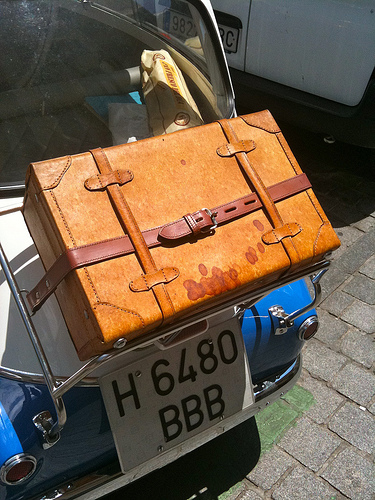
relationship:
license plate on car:
[148, 11, 263, 44] [152, 12, 361, 107]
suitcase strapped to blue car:
[18, 108, 343, 360] [0, 1, 339, 500]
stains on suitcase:
[171, 219, 266, 304] [18, 108, 343, 360]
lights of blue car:
[2, 450, 39, 486] [0, 1, 339, 500]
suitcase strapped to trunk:
[18, 108, 343, 360] [5, 149, 337, 440]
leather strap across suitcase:
[26, 152, 313, 290] [18, 108, 343, 360]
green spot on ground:
[240, 376, 320, 454] [229, 350, 374, 494]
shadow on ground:
[284, 115, 374, 228] [215, 119, 374, 498]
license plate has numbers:
[97, 316, 255, 473] [148, 327, 240, 394]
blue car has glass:
[0, 1, 339, 500] [2, 1, 233, 184]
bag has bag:
[137, 49, 205, 132] [137, 49, 205, 132]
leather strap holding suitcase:
[24, 172, 313, 304] [18, 108, 343, 360]